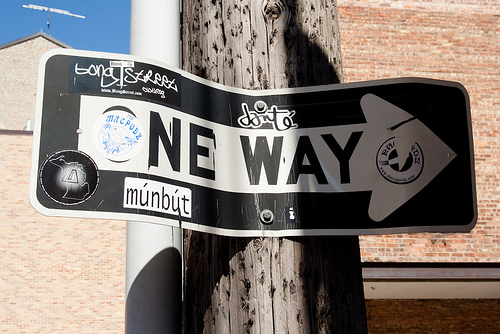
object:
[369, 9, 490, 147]
wall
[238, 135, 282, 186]
letter "w"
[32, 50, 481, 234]
sign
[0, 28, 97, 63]
roof.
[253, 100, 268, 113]
screws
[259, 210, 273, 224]
screws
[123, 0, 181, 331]
pole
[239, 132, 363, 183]
word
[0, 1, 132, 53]
blue sky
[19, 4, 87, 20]
antenna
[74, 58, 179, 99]
graffiti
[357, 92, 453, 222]
tip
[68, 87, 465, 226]
arrow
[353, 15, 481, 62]
bricks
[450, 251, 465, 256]
brick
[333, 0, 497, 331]
building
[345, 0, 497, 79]
brick wall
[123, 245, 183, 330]
shadow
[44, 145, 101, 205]
sticker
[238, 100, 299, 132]
graffiti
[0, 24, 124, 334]
building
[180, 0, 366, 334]
pole